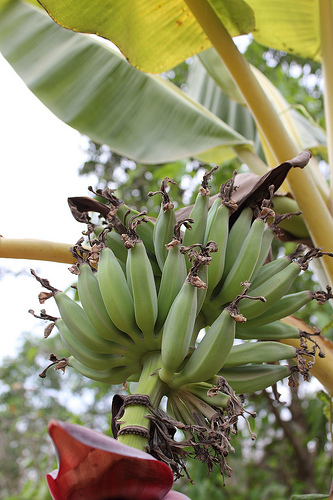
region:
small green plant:
[41, 169, 318, 455]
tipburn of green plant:
[36, 160, 325, 467]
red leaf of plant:
[45, 416, 174, 495]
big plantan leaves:
[4, 2, 331, 192]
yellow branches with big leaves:
[4, 7, 331, 364]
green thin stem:
[113, 371, 158, 453]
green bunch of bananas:
[53, 186, 309, 429]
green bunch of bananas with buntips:
[51, 174, 309, 445]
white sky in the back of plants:
[1, 5, 121, 361]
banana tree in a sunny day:
[6, 0, 331, 489]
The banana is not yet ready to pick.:
[149, 175, 179, 282]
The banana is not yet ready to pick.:
[121, 217, 158, 340]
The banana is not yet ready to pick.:
[153, 216, 193, 342]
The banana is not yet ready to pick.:
[91, 236, 142, 349]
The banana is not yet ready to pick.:
[68, 254, 133, 354]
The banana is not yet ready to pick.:
[38, 283, 126, 365]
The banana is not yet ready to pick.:
[158, 239, 210, 387]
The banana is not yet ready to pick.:
[168, 280, 257, 395]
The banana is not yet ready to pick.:
[212, 359, 312, 396]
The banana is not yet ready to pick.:
[201, 336, 309, 371]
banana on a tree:
[123, 219, 158, 344]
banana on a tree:
[151, 249, 210, 376]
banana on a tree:
[186, 305, 245, 391]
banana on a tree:
[219, 334, 305, 375]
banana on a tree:
[250, 288, 322, 333]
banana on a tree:
[248, 250, 312, 328]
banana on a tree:
[206, 203, 270, 324]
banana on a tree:
[193, 175, 251, 292]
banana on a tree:
[147, 182, 192, 270]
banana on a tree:
[110, 189, 154, 248]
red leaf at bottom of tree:
[37, 413, 185, 499]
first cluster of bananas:
[152, 258, 264, 390]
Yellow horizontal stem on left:
[1, 202, 84, 275]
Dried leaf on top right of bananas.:
[173, 143, 306, 225]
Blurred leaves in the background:
[3, 324, 89, 420]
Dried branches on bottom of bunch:
[114, 383, 229, 476]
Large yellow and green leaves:
[5, 0, 264, 155]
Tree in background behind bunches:
[261, 384, 329, 495]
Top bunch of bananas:
[106, 198, 320, 331]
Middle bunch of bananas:
[35, 255, 288, 359]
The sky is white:
[9, 191, 49, 249]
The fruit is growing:
[115, 250, 254, 383]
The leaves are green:
[254, 412, 309, 471]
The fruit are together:
[39, 189, 297, 412]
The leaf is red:
[47, 427, 120, 487]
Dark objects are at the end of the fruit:
[168, 218, 189, 246]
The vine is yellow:
[5, 217, 81, 263]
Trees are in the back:
[7, 345, 95, 449]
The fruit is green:
[96, 235, 257, 419]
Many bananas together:
[50, 191, 330, 466]